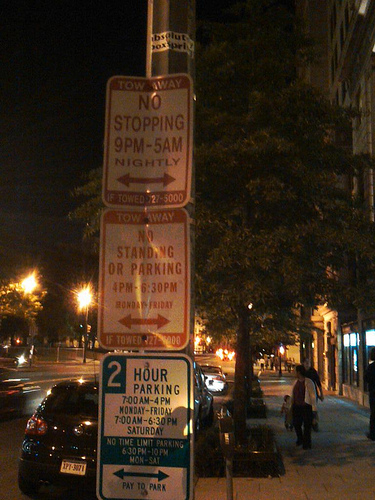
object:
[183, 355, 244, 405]
car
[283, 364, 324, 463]
woman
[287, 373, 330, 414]
jacket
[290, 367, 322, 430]
lady walking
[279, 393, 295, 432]
boy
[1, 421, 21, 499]
street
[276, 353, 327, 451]
family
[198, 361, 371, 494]
street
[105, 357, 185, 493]
words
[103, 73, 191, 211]
sign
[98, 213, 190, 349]
sign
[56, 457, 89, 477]
license plate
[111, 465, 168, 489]
arrow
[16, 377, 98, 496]
car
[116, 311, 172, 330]
arrows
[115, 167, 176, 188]
arrows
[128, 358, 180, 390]
white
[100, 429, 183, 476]
green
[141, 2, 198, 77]
pole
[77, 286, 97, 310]
light flare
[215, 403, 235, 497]
parking meter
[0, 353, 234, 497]
road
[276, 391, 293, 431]
kid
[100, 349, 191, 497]
signs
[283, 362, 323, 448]
lady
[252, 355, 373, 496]
sidewalk